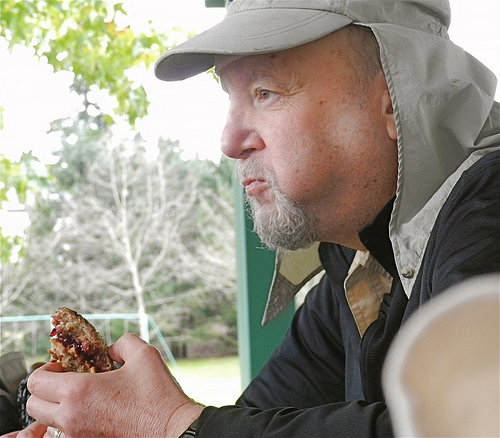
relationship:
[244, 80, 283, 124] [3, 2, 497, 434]
eye on man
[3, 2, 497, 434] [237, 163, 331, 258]
man has beard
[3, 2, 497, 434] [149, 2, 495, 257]
man wearing hat.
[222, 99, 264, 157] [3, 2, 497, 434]
nose of man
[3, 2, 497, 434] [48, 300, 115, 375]
man eating sandwich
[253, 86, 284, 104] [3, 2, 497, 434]
eye of man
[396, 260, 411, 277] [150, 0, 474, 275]
button on hat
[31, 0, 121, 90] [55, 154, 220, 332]
leaves on tree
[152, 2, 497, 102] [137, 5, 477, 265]
hat on head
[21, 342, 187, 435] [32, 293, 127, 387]
hand on sandwich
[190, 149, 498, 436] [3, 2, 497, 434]
jacket on man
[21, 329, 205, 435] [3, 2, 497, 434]
hand on man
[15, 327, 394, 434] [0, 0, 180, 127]
arm in leaves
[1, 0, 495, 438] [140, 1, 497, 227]
man wearing hood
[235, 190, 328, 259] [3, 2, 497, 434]
beard on man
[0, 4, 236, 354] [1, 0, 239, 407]
trees outside window